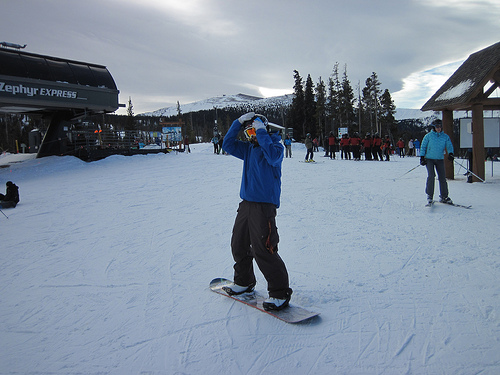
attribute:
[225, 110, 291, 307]
person — standing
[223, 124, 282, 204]
coat — blue, pale blue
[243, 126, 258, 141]
goggles — orange, brightly colored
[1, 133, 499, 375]
snow — white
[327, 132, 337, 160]
person — standing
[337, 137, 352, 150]
jacket — red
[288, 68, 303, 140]
pine tree — tall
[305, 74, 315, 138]
pine tree — tall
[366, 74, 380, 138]
pine tree — tall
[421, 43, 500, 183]
shelter — small, wood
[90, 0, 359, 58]
cloud — white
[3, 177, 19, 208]
person — sitting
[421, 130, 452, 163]
coat — light blue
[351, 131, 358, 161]
person — standing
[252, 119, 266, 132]
glove — gray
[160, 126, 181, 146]
sign — large